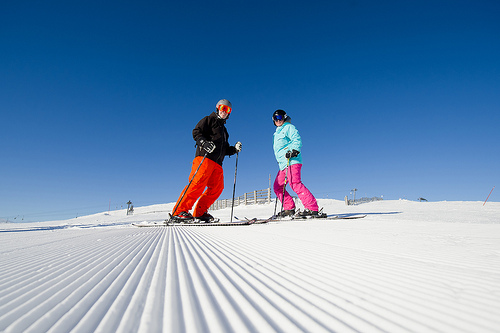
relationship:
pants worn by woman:
[273, 163, 319, 212] [272, 109, 319, 219]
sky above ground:
[4, 5, 495, 227] [0, 196, 498, 333]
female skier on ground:
[272, 109, 320, 217] [2, 196, 499, 327]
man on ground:
[171, 99, 243, 220] [2, 196, 499, 327]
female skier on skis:
[272, 109, 320, 217] [127, 210, 257, 232]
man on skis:
[171, 99, 243, 220] [227, 208, 370, 229]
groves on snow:
[0, 222, 486, 332] [8, 194, 490, 331]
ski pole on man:
[230, 150, 238, 222] [169, 96, 243, 228]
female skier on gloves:
[272, 109, 320, 217] [283, 148, 300, 160]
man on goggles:
[169, 96, 243, 228] [214, 102, 233, 117]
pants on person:
[170, 156, 225, 216] [169, 99, 243, 215]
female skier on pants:
[272, 109, 320, 217] [273, 163, 319, 213]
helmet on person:
[270, 108, 288, 120] [265, 104, 321, 219]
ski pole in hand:
[169, 151, 208, 222] [198, 139, 216, 153]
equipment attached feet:
[164, 208, 223, 228] [189, 204, 214, 221]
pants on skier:
[184, 160, 217, 215] [199, 89, 243, 145]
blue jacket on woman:
[272, 121, 303, 171] [272, 109, 319, 219]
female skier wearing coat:
[259, 100, 321, 219] [269, 126, 304, 166]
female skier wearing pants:
[259, 100, 321, 219] [273, 160, 316, 209]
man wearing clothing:
[171, 99, 243, 220] [162, 110, 238, 218]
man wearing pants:
[171, 99, 243, 220] [167, 157, 227, 220]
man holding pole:
[169, 96, 243, 228] [229, 140, 239, 224]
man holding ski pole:
[169, 96, 243, 228] [169, 151, 208, 222]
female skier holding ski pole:
[272, 109, 320, 217] [279, 152, 291, 218]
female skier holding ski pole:
[272, 109, 320, 217] [274, 195, 279, 217]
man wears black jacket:
[169, 96, 243, 228] [193, 115, 237, 165]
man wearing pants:
[169, 96, 243, 228] [172, 156, 225, 217]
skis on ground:
[131, 217, 257, 227] [1, 213, 484, 324]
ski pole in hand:
[164, 137, 217, 229] [204, 142, 209, 150]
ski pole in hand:
[227, 137, 242, 221] [232, 139, 242, 151]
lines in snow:
[135, 234, 289, 299] [4, 214, 477, 317]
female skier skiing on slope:
[272, 109, 320, 217] [8, 199, 481, 331]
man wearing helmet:
[169, 96, 243, 228] [216, 97, 235, 114]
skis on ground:
[130, 214, 258, 229] [0, 196, 498, 333]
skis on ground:
[231, 212, 368, 222] [0, 196, 498, 333]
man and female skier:
[169, 96, 243, 228] [272, 109, 320, 217]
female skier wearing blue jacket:
[272, 109, 320, 217] [271, 120, 301, 170]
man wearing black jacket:
[171, 99, 243, 220] [192, 111, 236, 166]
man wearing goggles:
[169, 96, 243, 228] [218, 104, 232, 114]